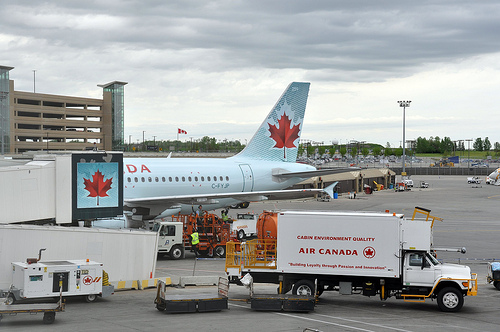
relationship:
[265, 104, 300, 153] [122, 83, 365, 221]
leaf on a airplane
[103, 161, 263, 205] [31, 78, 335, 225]
windows on airplane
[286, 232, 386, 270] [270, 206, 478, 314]
lettering on truck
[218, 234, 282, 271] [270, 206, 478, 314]
railing behind truck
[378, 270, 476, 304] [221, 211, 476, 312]
bars on truck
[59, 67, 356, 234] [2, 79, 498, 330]
airplane at airport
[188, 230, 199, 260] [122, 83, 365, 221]
man boarding airplane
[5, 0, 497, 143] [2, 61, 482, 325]
cloudy at airport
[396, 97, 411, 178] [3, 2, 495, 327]
floodlight in photo